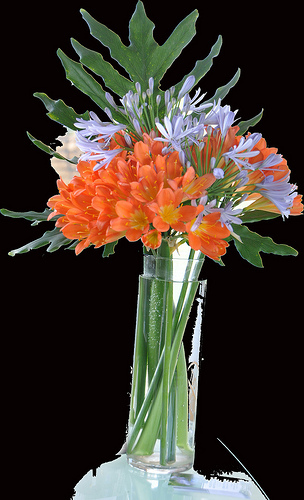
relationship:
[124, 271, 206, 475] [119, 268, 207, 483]
water in vase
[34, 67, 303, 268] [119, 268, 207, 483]
flowers in vase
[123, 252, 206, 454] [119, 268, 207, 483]
stems in vase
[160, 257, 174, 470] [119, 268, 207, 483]
stems in vase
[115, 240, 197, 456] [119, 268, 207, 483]
stems in vase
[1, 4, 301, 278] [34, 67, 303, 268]
leaves on flowers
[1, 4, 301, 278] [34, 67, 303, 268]
leaves in flowers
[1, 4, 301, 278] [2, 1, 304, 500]
leaves against background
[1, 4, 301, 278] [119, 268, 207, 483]
leaves in vase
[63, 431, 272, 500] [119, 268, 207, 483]
material under vase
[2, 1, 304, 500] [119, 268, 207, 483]
background with vase